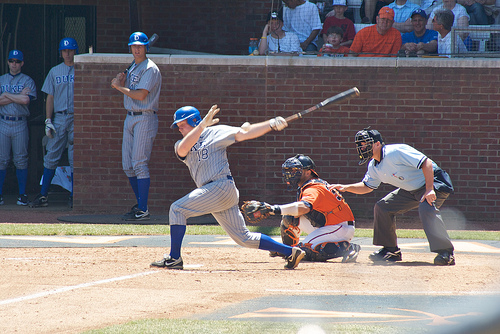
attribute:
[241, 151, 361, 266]
catcher — kneeling, bending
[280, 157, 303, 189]
catcher's mask — black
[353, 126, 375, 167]
catcher's mask — black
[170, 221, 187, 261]
sock — blue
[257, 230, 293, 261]
sock — blue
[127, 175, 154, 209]
sock — blue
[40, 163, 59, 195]
sock — blue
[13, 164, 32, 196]
sock — blue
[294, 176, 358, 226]
shirt — orange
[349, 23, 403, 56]
shirt — orange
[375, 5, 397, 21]
hat — orange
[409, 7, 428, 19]
hat — blue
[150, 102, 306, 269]
baseball player — blue, gray, squatting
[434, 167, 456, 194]
bag — blue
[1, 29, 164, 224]
baseball players — standing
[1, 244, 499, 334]
dirt — brown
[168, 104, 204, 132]
helmet — blue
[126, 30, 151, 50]
helmet — blue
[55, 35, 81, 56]
helmet — blue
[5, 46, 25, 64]
helmet — blue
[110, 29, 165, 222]
baseball player — blue, gray, standing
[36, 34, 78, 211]
baseball player — blue, gray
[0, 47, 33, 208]
baseball player — blue, gray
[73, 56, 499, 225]
wall — brick, red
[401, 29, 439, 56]
shirt — blue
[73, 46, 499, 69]
top — stone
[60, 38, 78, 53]
hat — blue